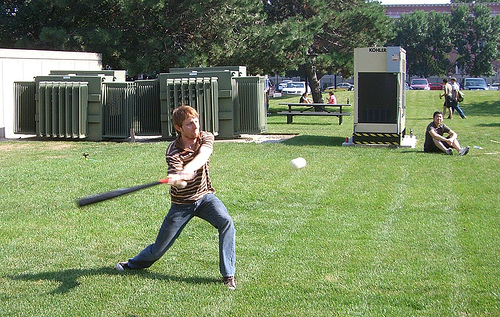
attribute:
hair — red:
[164, 104, 208, 120]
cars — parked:
[265, 61, 495, 104]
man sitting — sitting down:
[422, 110, 472, 158]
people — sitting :
[298, 90, 337, 104]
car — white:
[276, 77, 310, 97]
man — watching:
[418, 106, 470, 167]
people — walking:
[373, 52, 495, 174]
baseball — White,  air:
[292, 153, 309, 170]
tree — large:
[448, 13, 493, 93]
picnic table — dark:
[275, 102, 350, 123]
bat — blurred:
[67, 152, 159, 212]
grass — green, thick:
[1, 82, 498, 314]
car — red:
[401, 67, 497, 89]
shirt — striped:
[164, 126, 222, 195]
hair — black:
[430, 103, 444, 121]